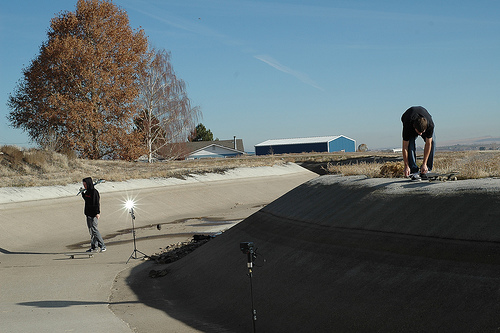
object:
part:
[126, 207, 155, 264]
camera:
[240, 242, 254, 254]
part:
[76, 188, 87, 197]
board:
[75, 179, 101, 196]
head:
[412, 116, 427, 135]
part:
[0, 248, 29, 254]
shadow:
[0, 247, 86, 254]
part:
[91, 222, 98, 229]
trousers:
[86, 215, 106, 249]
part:
[176, 145, 185, 152]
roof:
[131, 136, 247, 158]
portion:
[339, 139, 346, 147]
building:
[254, 134, 356, 155]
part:
[156, 85, 167, 90]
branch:
[153, 92, 168, 106]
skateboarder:
[79, 177, 106, 253]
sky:
[0, 0, 499, 156]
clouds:
[253, 46, 322, 90]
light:
[123, 200, 135, 210]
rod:
[402, 173, 423, 176]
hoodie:
[81, 176, 100, 217]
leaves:
[54, 44, 91, 99]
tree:
[4, 0, 149, 159]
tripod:
[125, 214, 154, 264]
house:
[479, 147, 485, 151]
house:
[134, 136, 244, 161]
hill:
[0, 144, 185, 187]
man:
[401, 106, 435, 182]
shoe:
[409, 172, 421, 182]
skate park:
[0, 158, 499, 333]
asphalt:
[0, 162, 499, 332]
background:
[0, 0, 498, 330]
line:
[120, 1, 330, 93]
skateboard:
[64, 252, 94, 259]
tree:
[129, 47, 203, 163]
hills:
[434, 135, 499, 151]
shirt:
[401, 105, 435, 140]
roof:
[254, 134, 356, 147]